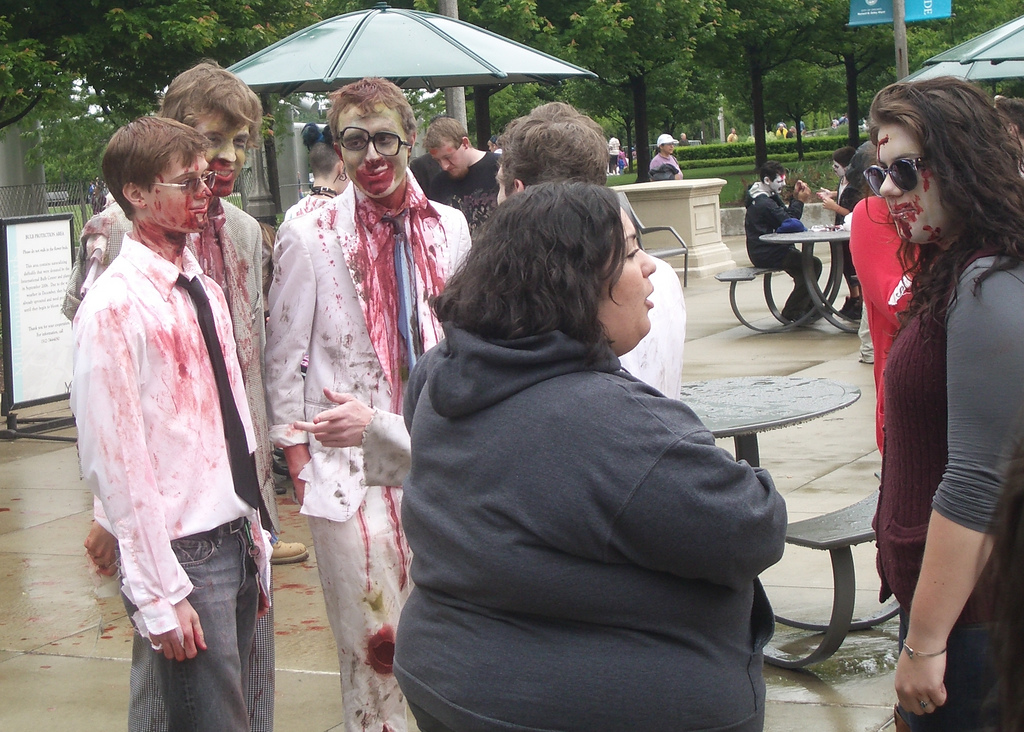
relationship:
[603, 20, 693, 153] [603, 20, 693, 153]
leaves on tree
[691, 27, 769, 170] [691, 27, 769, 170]
leaves on tree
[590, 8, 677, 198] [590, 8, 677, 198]
leaves on tree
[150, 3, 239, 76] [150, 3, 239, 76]
leaves on tree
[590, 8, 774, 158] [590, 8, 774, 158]
leaves on tree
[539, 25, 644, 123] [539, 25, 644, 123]
leaves on tree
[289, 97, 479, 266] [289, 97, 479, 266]
paint on boys face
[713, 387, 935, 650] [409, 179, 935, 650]
table behind women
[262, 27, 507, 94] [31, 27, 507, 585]
umbrella behind boys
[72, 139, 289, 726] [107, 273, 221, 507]
boy has tie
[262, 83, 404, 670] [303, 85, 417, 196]
boy has glasses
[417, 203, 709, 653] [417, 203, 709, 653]
lady wearing hoodie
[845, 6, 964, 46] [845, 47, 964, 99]
signs on a pole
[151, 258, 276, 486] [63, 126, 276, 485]
tie worn by boy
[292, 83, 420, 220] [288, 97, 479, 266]
boy wearing paint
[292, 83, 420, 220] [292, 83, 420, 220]
boy wearing glasses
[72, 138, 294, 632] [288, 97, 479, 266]
shirt covered with paint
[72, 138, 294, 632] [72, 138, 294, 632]
boy with a shirt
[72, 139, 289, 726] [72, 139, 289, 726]
boy dressed as boy